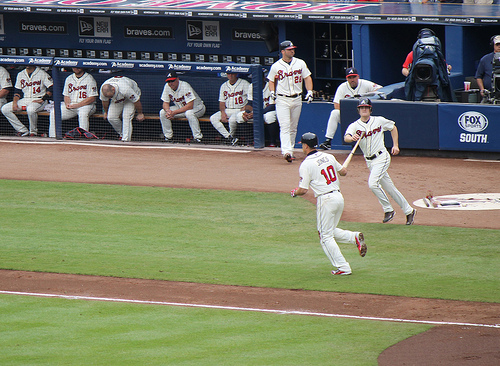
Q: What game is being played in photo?
A: Baseball.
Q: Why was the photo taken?
A: To show a game.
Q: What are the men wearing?
A: Baseball uniforms.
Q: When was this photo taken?
A: In the daytime.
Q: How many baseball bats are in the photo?
A: One.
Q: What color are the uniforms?
A: White.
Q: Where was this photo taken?
A: At a baseball stadium.